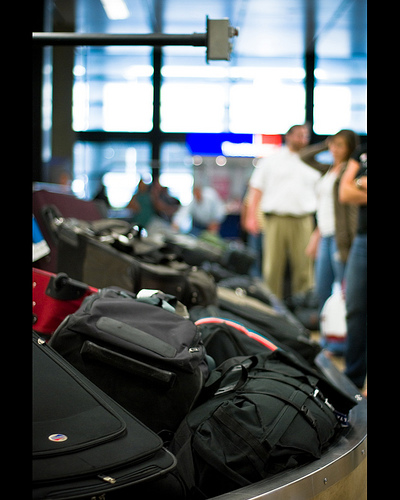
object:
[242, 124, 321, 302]
man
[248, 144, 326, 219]
shirt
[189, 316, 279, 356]
stripe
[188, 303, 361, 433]
bag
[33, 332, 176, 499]
bags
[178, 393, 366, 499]
rack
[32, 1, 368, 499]
airport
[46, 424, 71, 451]
decal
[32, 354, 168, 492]
suitcase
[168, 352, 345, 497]
bag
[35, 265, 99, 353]
suitcase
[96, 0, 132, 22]
light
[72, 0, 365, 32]
ceiling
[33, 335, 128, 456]
mat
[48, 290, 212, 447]
suitcase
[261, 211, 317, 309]
pants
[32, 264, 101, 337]
luggage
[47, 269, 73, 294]
wheels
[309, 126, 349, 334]
woman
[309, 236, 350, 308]
jeans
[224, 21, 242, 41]
button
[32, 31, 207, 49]
pole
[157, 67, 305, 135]
light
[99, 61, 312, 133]
windows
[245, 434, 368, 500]
side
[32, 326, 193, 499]
luggage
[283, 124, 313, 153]
head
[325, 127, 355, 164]
head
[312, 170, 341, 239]
shirt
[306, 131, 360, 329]
people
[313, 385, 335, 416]
metal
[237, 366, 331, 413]
belt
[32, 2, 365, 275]
background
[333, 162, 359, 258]
shirt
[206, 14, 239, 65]
camera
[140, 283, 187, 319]
tag